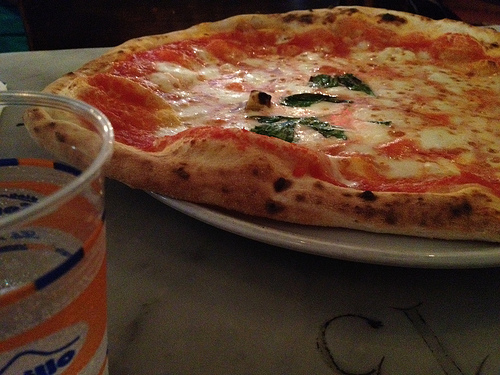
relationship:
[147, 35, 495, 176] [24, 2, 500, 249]
cheese across pizza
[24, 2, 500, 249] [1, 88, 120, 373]
pizza near cup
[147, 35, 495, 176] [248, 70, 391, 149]
cheese with basil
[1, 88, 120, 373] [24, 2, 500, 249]
cup near pizza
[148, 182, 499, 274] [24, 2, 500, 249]
plate under pizza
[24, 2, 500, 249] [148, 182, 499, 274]
pizza above plate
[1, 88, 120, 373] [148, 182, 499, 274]
cup near plate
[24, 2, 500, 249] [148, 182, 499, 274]
pizza laying on plate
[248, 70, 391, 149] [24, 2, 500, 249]
basil laying on pizza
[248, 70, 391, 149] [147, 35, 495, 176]
basil with cheese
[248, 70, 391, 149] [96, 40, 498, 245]
basil on pizza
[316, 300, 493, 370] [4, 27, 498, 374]
"cl" on table